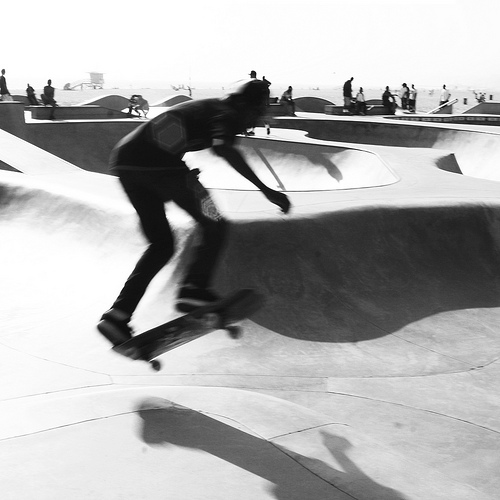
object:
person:
[353, 86, 368, 117]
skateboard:
[112, 286, 265, 371]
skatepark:
[0, 77, 500, 500]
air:
[0, 0, 499, 498]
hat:
[230, 78, 272, 116]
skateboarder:
[96, 74, 297, 346]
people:
[342, 76, 354, 105]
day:
[0, 0, 500, 500]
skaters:
[382, 85, 398, 114]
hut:
[87, 71, 105, 88]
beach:
[0, 71, 499, 109]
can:
[313, 87, 320, 90]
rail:
[387, 110, 500, 136]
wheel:
[228, 326, 242, 340]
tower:
[189, 69, 193, 86]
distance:
[0, 22, 500, 130]